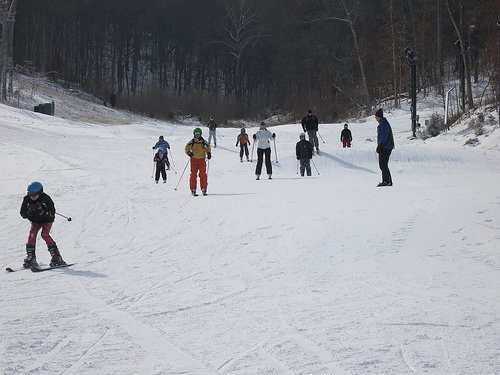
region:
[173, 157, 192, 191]
a metal ski pole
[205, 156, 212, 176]
a metal ski pole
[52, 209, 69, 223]
a metal ski pole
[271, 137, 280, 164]
a metal ski pole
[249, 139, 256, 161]
a metal ski pole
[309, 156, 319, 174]
a metal ski pole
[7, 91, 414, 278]
people skiing on the snow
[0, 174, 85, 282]
person wearing blue helmet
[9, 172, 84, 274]
person holding a snow pole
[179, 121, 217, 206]
person wearing yellow and orange suit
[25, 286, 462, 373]
marks of skies on the snow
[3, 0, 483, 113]
a forest behind a field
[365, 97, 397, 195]
man wearing a blue jacket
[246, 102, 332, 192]
the people holding poles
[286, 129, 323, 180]
person wearing black jacket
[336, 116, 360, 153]
person wearing black clothes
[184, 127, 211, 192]
Skier in yellow coat and orange pants.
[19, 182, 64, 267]
Kid in black jacket and blue helmet leaning down.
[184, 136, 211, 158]
A yellow jacket.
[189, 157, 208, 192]
Orange pants.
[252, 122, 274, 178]
A person in a white coaat and black pants.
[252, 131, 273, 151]
A white coat.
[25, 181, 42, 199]
Blue helmet on a kid.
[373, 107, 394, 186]
A man standing sideways in a blue coat and black hat.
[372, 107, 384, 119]
Black cap on a man standing sideways.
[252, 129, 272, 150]
A white winter coat.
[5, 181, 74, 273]
a skier going downhill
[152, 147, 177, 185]
a skier in snow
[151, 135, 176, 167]
a skier in snow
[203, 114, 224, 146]
a skier in snow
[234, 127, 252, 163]
a skier in snow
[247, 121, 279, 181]
a skier in snow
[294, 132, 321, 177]
a skier in snow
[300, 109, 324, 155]
a skier in snow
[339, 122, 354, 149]
a skier in snow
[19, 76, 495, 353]
cross country track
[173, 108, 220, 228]
person wearing a yellow jacket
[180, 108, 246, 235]
skier wearing orange snow pants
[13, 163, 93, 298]
child in a blue helmet